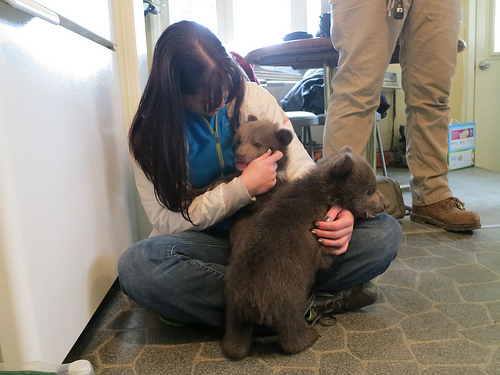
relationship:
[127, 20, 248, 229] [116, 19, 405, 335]
hair of girl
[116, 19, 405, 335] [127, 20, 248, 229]
girl with hair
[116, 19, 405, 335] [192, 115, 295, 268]
girl touching bear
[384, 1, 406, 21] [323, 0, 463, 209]
keys on trousers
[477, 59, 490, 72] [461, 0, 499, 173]
doorknob on door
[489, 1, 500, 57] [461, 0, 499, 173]
window on door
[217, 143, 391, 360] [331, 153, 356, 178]
bear has ear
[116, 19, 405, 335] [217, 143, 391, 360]
girl holding bear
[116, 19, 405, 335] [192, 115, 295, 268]
girl holding bear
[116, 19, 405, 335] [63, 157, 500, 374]
girl sitting on floor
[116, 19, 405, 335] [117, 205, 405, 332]
girl wearing jeans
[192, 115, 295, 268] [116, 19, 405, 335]
bear sitting on girl